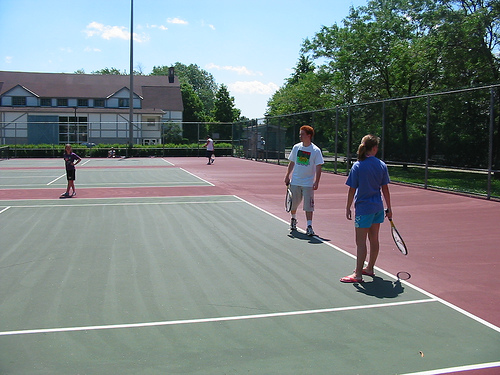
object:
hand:
[384, 210, 393, 220]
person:
[258, 135, 266, 162]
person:
[201, 134, 216, 165]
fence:
[0, 119, 242, 160]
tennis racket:
[284, 181, 293, 212]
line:
[201, 178, 216, 187]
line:
[395, 356, 498, 375]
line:
[11, 199, 247, 211]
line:
[437, 296, 500, 332]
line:
[0, 295, 441, 339]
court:
[0, 150, 499, 373]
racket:
[383, 209, 409, 256]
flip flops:
[339, 272, 366, 282]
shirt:
[343, 156, 392, 216]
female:
[338, 131, 396, 285]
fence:
[229, 85, 499, 203]